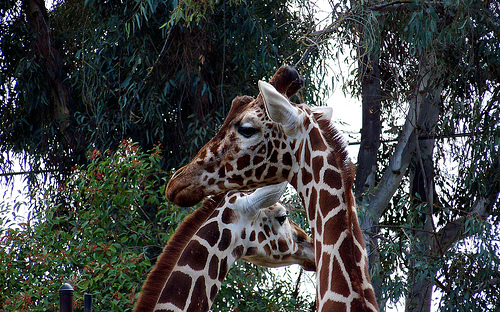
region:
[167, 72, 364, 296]
Two giraffes next to each other.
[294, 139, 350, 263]
The giraffe has brown spots.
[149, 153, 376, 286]
The giraffe is brown and white.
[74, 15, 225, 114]
Green leaveson the tree.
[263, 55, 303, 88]
Horns on the giraffe.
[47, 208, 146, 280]
Brown leaves on the tree.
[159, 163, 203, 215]
Mouth of the giraffe.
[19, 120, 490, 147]
Wire running thru the trees.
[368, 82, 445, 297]
Tree trunk of the trees.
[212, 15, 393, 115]
The sky is clear.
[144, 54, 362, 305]
two giraffes close together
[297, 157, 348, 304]
brown and white spots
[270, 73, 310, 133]
giraffe has white ears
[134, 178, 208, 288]
giraffe has brown mane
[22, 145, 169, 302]
red flowers on tree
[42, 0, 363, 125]
thick green leaves on tree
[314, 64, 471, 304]
thick grey trunk behind giraffes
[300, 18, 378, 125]
grey and white sky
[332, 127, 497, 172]
black power line behind trees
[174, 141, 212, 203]
giraffe has brown nose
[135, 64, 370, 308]
Two giraffes standing beside one another.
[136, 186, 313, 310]
A giraffe standing below another giraffe.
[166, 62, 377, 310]
A giraffe standing above another giraffe.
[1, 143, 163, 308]
A bush with green and red leaves in the background of two giraffes.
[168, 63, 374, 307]
A white giraffe with brown spots.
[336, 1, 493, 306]
Two trees in the background of two giraffes.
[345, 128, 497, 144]
An electrical wire running thru trees.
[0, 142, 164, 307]
A bush with bright green and red leaves.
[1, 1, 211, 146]
Several trees in the background of two giraffes.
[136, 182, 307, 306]
A giraffe looking towards trees.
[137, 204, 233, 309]
the long neck of the giraffe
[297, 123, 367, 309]
the long neck of the giraffe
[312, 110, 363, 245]
the brown mane of the giraffe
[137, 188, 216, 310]
the brown mane of the giraffe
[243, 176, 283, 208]
the white ear of the giraffe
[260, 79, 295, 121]
the white ear of the giraffe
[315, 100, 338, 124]
the white ear of the giraffe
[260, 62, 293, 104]
the brown horn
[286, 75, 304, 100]
the white ear of the giraffe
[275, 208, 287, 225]
the brown eye of the giraffe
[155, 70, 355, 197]
a white and brown giraffe head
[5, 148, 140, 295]
a green and orange leafy tree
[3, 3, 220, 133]
a dark green tree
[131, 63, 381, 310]
a pair of tall giraffe heads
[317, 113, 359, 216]
a furry brown giraffe mane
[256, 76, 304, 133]
a white giraffe ear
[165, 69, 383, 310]
a long giraffe neck and head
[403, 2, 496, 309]
a long white tree branch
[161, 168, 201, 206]
a brown giraffe mouth